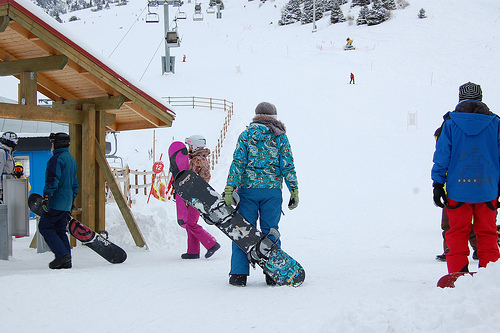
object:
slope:
[288, 0, 453, 327]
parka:
[226, 114, 298, 191]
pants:
[444, 194, 498, 276]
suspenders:
[442, 196, 465, 210]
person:
[222, 102, 301, 286]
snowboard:
[173, 170, 306, 285]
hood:
[251, 117, 286, 137]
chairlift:
[106, 3, 181, 75]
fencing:
[106, 95, 235, 198]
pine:
[363, 7, 388, 25]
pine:
[332, 6, 345, 24]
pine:
[416, 6, 426, 19]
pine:
[278, 4, 298, 25]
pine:
[302, 0, 322, 24]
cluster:
[277, 0, 409, 24]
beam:
[3, 54, 68, 77]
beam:
[35, 95, 126, 109]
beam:
[0, 102, 116, 126]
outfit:
[226, 116, 298, 276]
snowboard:
[28, 192, 127, 264]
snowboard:
[169, 141, 190, 227]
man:
[348, 71, 356, 86]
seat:
[163, 31, 180, 47]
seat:
[144, 12, 160, 25]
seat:
[174, 10, 188, 21]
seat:
[191, 9, 205, 22]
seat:
[105, 127, 125, 179]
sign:
[151, 160, 163, 174]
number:
[152, 163, 163, 173]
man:
[342, 36, 357, 52]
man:
[432, 83, 498, 288]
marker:
[406, 112, 418, 125]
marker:
[234, 64, 241, 72]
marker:
[316, 44, 326, 53]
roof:
[0, 2, 176, 133]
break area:
[3, 0, 174, 271]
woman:
[181, 133, 221, 259]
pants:
[182, 201, 218, 253]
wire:
[135, 2, 171, 93]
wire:
[102, 4, 133, 72]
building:
[3, 95, 88, 220]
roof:
[3, 132, 110, 152]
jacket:
[431, 109, 497, 203]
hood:
[450, 110, 496, 137]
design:
[266, 251, 302, 285]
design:
[245, 134, 264, 154]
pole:
[162, 0, 173, 74]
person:
[38, 132, 79, 268]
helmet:
[186, 134, 206, 148]